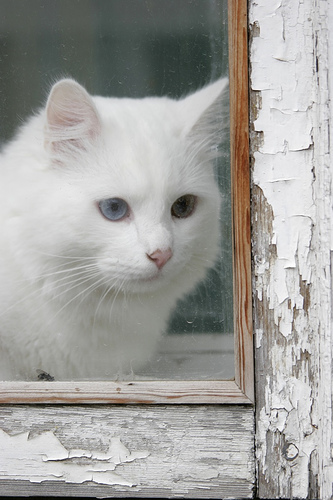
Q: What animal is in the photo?
A: A cat.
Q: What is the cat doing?
A: Looking out the window.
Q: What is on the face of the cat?
A: Whiskers.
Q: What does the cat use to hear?
A: The ears.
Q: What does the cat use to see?
A: The eyes.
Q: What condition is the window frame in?
A: Poor.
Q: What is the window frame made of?
A: Wood.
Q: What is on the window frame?
A: Paint.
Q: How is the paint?
A: Chipped.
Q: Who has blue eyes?
A: The cat.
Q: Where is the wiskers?
A: On cat.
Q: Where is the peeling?
A: On frame.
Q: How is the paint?
A: Peeling.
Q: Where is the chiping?
A: On frame.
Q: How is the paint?
A: Chipping.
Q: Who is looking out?
A: Cat.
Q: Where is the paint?
A: Frame.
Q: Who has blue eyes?
A: Cat.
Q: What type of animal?
A: Cat.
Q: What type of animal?
A: Cat.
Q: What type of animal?
A: Cat.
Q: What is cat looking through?
A: Window.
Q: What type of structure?
A: Window frame.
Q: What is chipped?
A: Paint.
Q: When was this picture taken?
A: During the day.